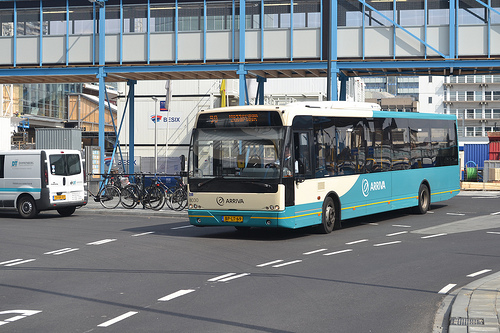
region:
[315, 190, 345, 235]
the wheel of a bus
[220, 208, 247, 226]
a yellow license plate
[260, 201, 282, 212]
the headlights on the bus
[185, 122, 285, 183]
the windshield of the bus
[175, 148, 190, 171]
a side view mirror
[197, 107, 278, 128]
a digital display on the bus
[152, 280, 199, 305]
a white stripe on the road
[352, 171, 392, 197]
white writing on the bus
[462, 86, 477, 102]
a window on the building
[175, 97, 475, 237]
a bus on the road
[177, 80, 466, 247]
Bus is blue and white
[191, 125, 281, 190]
Front windshield of bus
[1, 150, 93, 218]
White truck beside bus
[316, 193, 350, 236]
Front left wheel of bus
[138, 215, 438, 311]
White lines in street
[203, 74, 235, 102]
Yellow pole in background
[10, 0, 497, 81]
Blue poles above bus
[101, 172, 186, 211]
Bikes next to bus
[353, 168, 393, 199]
white logo on side of bus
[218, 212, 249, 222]
Yellow license plate of bus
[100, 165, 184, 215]
bicycles parked on the roadside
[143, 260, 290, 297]
broken white lines on street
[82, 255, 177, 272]
gray color on street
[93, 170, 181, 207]
bikes parked at rack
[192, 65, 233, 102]
large yellow construction equipment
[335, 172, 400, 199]
name at side of blue bus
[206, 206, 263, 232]
small yellow license plate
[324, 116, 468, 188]
extremely large window at side of bus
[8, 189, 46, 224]
black wheel in vehicle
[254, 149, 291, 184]
black steering wheel in bus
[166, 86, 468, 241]
large passenger bus in street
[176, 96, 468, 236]
Bus is blue and white.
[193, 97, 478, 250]
The bus has a tire.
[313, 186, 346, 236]
The tire is round.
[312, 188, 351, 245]
The tire is black.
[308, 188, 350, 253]
The tire is inflated.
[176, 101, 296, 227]
Bus has a windshield.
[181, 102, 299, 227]
The windshield is clear.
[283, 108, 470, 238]
Windows on bus are tinted.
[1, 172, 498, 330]
Painted lines on a street.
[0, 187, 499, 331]
Painted lines are white.